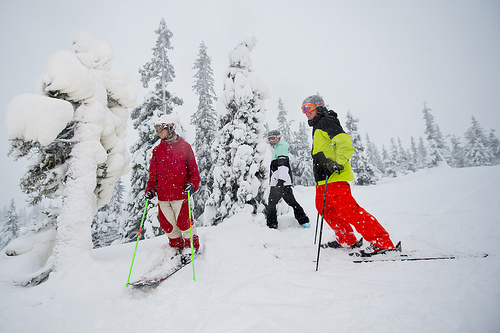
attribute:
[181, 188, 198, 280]
ski sticks — green, neon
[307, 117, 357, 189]
coat — lime green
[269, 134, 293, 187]
jacket — black, white, light aqua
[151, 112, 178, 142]
helmet — white, black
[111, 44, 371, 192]
trees — snow covered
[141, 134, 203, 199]
jacket — red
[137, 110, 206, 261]
boy — young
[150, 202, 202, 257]
pants — white, red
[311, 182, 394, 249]
pants — red, ski pants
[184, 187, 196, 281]
ski stick — neon, green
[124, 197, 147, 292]
ski stick — neon, green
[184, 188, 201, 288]
ski stick — neon, green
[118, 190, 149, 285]
ski stick — neon, green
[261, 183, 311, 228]
black pants — ski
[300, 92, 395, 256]
boy — young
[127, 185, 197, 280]
sticks — green, neon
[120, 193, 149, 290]
stick — neon, green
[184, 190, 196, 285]
stick — neon, green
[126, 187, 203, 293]
ski sticks — neon, green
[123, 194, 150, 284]
ski stick — green, neon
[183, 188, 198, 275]
ski stick — green, neon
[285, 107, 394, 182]
jacket — black, lime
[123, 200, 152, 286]
stick — neon, green